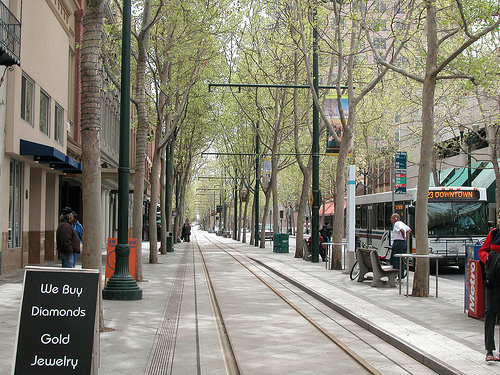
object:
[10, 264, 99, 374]
sign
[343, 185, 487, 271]
bus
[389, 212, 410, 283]
man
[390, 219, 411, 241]
shirt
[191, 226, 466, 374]
tracks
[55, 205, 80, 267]
man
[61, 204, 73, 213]
hat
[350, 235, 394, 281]
bike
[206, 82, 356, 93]
cable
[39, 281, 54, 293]
letter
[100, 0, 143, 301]
pole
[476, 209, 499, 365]
person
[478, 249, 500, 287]
jacket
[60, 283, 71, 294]
letter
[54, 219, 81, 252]
jacket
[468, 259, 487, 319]
box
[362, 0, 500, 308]
tree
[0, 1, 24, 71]
balcony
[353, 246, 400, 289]
bench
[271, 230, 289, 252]
can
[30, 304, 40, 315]
letter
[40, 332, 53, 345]
letter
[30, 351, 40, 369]
letter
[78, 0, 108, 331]
tree trunk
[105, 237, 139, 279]
sign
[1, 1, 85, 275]
building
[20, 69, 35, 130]
window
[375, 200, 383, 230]
window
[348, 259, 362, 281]
wheel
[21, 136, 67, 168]
awning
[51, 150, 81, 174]
awning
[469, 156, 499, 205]
awning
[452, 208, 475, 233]
man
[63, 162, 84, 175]
awning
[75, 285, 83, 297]
letter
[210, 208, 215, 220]
streetlight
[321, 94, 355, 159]
banner